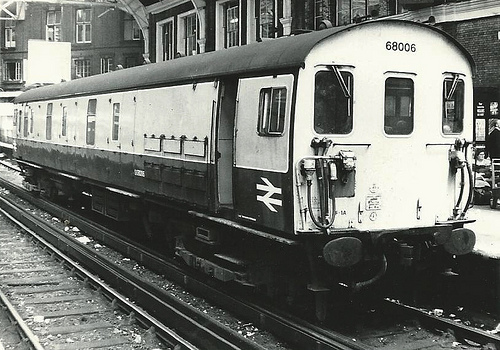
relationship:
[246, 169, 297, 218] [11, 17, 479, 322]
arrows on train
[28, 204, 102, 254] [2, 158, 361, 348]
litter between rail way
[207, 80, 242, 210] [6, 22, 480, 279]
door on side of train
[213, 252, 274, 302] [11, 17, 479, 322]
wheels under train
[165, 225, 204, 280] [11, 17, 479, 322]
wheels under train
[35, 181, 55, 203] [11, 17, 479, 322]
wheels under train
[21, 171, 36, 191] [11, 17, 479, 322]
wheels under train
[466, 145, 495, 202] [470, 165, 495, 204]
woman sitting in chair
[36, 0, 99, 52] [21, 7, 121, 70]
windows on brick building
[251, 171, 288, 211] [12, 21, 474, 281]
pattern on car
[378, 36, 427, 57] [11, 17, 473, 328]
number on train car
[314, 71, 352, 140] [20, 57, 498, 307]
window on car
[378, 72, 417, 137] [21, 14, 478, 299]
window on train car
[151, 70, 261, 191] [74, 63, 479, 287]
door on side of train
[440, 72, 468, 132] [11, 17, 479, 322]
window on a train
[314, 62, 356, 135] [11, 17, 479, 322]
window on a train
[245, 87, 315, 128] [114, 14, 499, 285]
window on a train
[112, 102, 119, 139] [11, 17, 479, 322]
window on a train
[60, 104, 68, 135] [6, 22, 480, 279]
window on a train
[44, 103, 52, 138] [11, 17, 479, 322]
window on a train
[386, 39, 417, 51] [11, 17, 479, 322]
number on a train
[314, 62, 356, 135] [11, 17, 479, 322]
window in front of train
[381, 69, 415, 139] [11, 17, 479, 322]
window in front of train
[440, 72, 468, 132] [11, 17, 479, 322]
window in front of train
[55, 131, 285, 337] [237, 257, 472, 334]
gravel and rocks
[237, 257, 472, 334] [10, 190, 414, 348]
rocks on tracks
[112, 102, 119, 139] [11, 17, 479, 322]
window on side of train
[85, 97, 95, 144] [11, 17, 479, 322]
window on side of train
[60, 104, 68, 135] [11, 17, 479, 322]
window on side of train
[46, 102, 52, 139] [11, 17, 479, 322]
window on side of train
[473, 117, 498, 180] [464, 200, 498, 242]
people on walkway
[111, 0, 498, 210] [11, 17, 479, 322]
building on side of train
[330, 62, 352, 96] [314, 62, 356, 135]
wipers on window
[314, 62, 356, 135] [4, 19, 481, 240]
window of train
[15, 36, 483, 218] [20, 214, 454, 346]
train on train tracks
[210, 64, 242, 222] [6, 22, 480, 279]
door on train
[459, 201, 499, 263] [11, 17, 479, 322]
platform next to train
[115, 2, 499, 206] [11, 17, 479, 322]
station behind train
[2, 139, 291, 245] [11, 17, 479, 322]
strip running down train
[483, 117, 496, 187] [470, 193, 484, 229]
person standing on platform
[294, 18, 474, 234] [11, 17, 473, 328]
backside of train car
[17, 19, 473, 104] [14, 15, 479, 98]
top of train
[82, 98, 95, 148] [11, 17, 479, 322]
window on train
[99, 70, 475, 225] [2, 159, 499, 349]
train on track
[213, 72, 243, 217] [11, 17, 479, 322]
door on train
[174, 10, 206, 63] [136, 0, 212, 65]
window on building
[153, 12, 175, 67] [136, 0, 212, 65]
window on building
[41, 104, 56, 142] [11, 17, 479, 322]
window on side of train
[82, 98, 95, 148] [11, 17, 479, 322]
window on side of train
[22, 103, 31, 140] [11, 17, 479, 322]
window on side of train